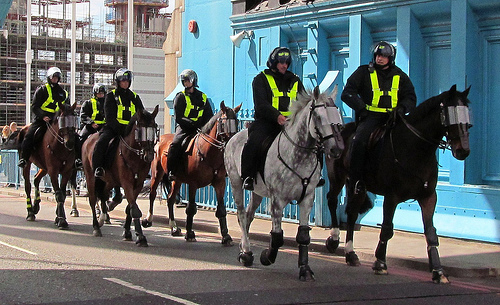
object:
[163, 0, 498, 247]
building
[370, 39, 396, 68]
helmet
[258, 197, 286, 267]
leg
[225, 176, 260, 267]
leg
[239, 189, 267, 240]
leg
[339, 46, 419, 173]
policeman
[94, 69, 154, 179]
policeman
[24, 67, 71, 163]
policeman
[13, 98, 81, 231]
horse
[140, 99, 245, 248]
horse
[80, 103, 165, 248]
horse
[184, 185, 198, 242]
leg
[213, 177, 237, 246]
leg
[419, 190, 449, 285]
leg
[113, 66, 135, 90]
helmet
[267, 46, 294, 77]
helmet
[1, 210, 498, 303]
shadow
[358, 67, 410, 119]
safety vest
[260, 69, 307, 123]
safety vest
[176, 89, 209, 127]
safety vest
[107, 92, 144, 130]
safety vest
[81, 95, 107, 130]
safety vest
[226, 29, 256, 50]
speaker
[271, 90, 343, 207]
harness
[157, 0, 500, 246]
wall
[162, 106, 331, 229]
gate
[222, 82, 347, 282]
horse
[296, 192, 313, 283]
leg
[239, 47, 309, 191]
man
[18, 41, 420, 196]
street patrol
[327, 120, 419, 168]
horseback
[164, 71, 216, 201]
man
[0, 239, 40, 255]
lane separator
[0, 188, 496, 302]
road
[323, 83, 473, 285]
horse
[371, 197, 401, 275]
leg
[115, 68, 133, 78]
shield